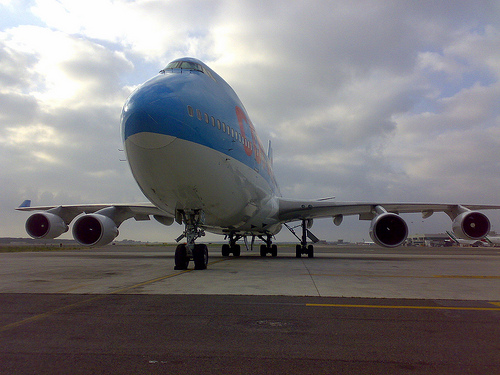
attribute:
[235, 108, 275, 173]
writing — red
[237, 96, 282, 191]
letters — red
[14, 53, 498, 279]
aircraft — large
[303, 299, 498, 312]
stripe — yellow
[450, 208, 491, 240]
airplane engine — round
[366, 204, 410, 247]
airplane engine — round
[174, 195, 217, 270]
gear — landing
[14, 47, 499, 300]
airplane — large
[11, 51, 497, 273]
plane — large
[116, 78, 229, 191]
nose — shiny blue, airplane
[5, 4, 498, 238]
clouds — white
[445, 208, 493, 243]
engine — airplane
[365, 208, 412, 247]
engine — airplane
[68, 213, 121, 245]
engine — airplane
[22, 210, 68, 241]
engine — airplane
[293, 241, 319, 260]
landing gear — rear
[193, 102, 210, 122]
window — rectangular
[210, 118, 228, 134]
window — rectangular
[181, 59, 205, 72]
window — airplane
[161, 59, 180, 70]
window — airplane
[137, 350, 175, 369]
pool — small, water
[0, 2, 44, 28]
patch — small, clear, blue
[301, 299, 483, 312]
line — yellow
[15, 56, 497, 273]
airplane — jet, blue, painted